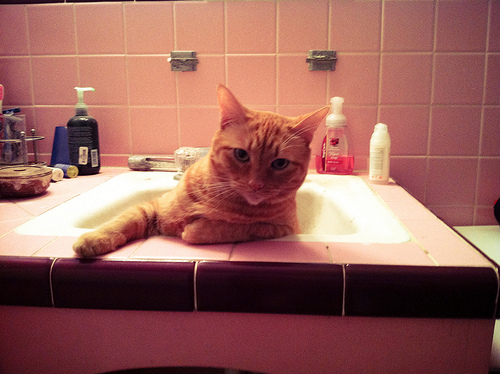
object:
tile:
[0, 253, 54, 306]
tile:
[52, 257, 194, 313]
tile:
[195, 259, 344, 315]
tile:
[342, 262, 499, 321]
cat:
[73, 83, 331, 259]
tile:
[375, 43, 436, 111]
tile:
[373, 47, 436, 120]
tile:
[338, 46, 384, 90]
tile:
[219, 47, 281, 110]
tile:
[73, 48, 132, 108]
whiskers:
[180, 172, 238, 202]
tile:
[377, 2, 441, 57]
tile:
[119, 47, 163, 112]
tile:
[24, 46, 81, 83]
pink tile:
[3, 263, 344, 311]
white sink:
[311, 188, 370, 245]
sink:
[94, 188, 372, 244]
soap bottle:
[313, 86, 358, 180]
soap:
[367, 121, 394, 184]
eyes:
[224, 140, 299, 175]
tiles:
[209, 12, 284, 82]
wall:
[201, 10, 262, 110]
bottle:
[65, 85, 100, 176]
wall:
[2, 3, 497, 226]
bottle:
[367, 120, 391, 188]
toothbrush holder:
[1, 104, 46, 166]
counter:
[0, 130, 500, 257]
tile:
[425, 54, 495, 84]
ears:
[212, 83, 248, 126]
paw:
[70, 218, 112, 259]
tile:
[383, 209, 451, 262]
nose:
[240, 180, 267, 191]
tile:
[127, 98, 177, 154]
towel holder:
[167, 49, 338, 73]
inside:
[27, 82, 486, 289]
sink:
[28, 87, 496, 313]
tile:
[22, 3, 80, 57]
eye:
[231, 144, 253, 164]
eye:
[265, 157, 292, 171]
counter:
[5, 165, 497, 268]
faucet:
[173, 146, 201, 179]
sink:
[72, 207, 95, 219]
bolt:
[166, 57, 177, 67]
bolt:
[188, 59, 198, 66]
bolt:
[301, 56, 315, 65]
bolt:
[326, 57, 337, 65]